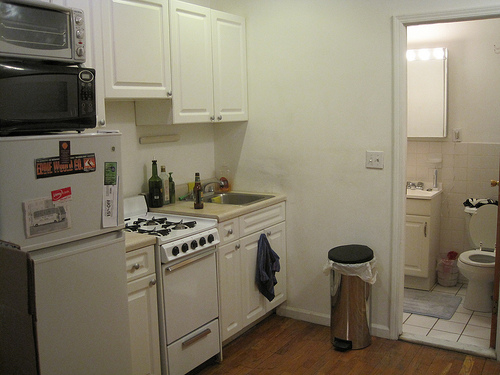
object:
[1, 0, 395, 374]
kitchen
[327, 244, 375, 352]
trashcan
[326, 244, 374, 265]
lid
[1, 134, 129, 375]
fridge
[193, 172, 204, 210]
bottle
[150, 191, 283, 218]
counter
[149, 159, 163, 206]
bottle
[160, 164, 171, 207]
bottle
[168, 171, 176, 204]
bottle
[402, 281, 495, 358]
floor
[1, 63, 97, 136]
microwave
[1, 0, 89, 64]
microwave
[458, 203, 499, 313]
toilet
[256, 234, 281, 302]
towel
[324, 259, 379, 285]
bag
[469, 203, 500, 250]
lid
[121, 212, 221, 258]
stove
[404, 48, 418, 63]
light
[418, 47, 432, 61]
light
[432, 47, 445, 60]
light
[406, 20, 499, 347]
bathroom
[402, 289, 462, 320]
mat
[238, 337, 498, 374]
floor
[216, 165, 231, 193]
bottle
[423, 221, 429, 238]
handle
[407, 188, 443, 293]
cabinet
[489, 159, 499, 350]
door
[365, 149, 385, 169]
lightswitch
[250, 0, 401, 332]
wall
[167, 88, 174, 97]
handle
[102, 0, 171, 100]
cupboards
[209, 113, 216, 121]
handle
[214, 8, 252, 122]
cupboards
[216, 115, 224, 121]
handle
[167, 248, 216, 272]
handle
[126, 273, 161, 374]
cupboards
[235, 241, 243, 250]
handle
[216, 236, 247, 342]
cupboards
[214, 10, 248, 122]
door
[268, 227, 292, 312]
door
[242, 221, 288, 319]
cupboard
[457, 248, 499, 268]
toilet-seat